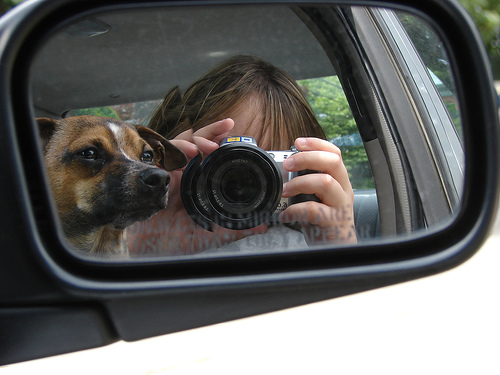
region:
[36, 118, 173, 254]
the dog looks out of the window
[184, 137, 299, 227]
the girl takes a picture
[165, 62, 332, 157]
the girl has light hair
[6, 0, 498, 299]
the photo is in the side mirror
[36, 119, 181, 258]
the dog is brown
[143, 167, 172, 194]
the dog has a black nose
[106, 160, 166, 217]
the mussel is black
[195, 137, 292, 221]
the camera is black and silver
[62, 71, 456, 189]
the trees in the background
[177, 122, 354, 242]
the girl has small fingers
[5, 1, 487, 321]
Selfie photo of a woman and dog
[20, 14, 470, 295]
Selfie photo in a passenger-side car mirror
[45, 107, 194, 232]
Dog with black eyes and nose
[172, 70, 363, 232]
Camera with wide angle lens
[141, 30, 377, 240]
Woman has dark brown hair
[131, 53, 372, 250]
Woman is European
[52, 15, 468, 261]
The car's interior is gray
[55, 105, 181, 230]
The dog's hair is brown and black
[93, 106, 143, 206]
The dog has a white steak between his eyes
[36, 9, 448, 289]
The woman and the dog are inside of the car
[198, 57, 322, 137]
straight, thin, brown hair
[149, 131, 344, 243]
hands holding a camera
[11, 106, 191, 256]
dog looking our of a car window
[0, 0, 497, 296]
side mirror on a car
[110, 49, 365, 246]
person holding a camera in a car window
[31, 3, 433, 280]
reflection of a car window in a mirror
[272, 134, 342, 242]
four fingers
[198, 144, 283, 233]
lens on a camera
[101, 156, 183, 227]
dog's snout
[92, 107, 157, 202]
white strip of fur on dog's face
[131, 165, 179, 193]
Dog's cold black nose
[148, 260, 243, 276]
Black rim at the bottom of the car mirror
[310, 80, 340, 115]
Green tree that can be seen through the rear window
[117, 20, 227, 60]
Roof/ceiling of the car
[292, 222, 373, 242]
The word 'APPEAR' on the mirror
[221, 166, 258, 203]
Lens of the camera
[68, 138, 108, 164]
Dog's right eye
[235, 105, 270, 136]
Photographer's forehead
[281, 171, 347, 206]
Photographer's left ring finger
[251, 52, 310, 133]
Photographer's stringy brown hair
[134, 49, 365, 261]
an old fashioned selfie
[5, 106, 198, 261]
a dog in the car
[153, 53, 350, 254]
a girl with man hands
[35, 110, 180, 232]
a handsome dog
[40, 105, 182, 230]
a focused dog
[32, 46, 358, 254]
a girl and her dog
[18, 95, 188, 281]
a dog in a car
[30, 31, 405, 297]
a selfie from theback seat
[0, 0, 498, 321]
a view from the mirror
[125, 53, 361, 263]
a girl with messy hair